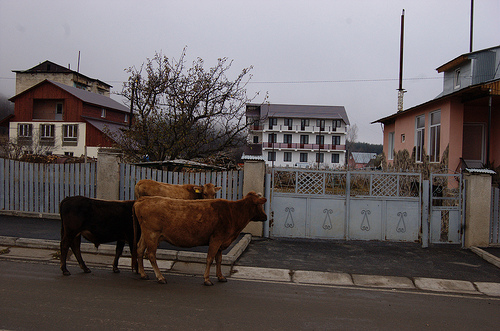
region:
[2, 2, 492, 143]
light blue sky over houses and trees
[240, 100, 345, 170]
white building with windows and terraces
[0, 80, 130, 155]
slanted roof over brown and yellow building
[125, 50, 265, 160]
tree with dark branches and small leaves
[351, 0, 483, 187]
pink house with black poles on roof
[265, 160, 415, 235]
gate with latticework and curlicues by driveway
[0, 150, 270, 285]
brown cows walking by picket fencing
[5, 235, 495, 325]
dark paving on street bordered with cement squares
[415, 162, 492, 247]
door between metal pole and cement column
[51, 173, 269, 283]
smaller and darker cow following other two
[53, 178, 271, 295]
cattle on the street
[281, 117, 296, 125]
windows on a building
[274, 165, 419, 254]
a gate across a driveway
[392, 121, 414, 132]
a pink building exterior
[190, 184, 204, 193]
yellow tag on an animals ear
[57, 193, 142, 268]
a black bull on the road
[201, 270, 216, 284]
the hoof of a cow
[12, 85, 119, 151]
a red and white building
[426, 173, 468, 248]
a white yard fence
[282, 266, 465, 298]
cement drainage ditch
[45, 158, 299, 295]
three cows standing on the street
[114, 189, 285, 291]
brown cow on the street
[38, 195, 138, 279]
black cow on the street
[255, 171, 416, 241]
grey fence on the street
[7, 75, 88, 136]
brick side to house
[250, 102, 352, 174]
white house by street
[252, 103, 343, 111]
grey roof of house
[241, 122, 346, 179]
windows on side of house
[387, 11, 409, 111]
large brown poles sticking up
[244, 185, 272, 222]
large brown head of cow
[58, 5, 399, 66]
The sky is the color gray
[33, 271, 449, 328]
The street is made of asphalt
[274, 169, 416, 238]
The gate is the color gray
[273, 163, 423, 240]
The gate is made of metal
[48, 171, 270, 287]
The cows in the middle of the street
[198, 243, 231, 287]
The front legs of the cow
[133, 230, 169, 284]
The back legs of the cow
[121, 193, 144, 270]
The tail of the cow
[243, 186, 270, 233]
The head of the cow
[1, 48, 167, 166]
The house is behind the gate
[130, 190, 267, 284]
a brown cow facing the right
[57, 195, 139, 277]
a dark brown bull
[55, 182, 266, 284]
cattle walking down the side of a road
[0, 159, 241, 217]
a gray colored wooden fence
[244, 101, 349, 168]
a three story white house with a gray roof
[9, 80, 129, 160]
a red and white building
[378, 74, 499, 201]
a peach colored house with four windows on the side of house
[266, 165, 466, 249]
a dirty white gate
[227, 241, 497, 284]
a paved driveway entrance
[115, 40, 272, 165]
a nearly bear tree